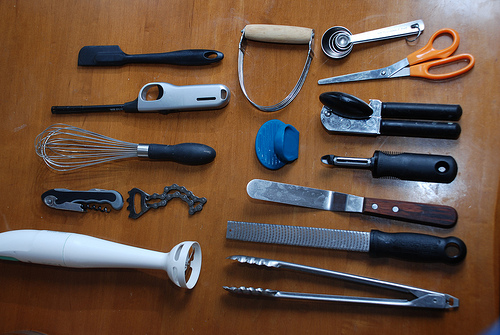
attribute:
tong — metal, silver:
[218, 260, 469, 302]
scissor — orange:
[297, 32, 482, 95]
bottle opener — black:
[132, 180, 227, 221]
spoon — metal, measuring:
[288, 13, 422, 69]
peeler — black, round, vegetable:
[302, 141, 475, 179]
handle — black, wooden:
[399, 84, 479, 132]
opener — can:
[312, 95, 465, 152]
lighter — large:
[33, 61, 232, 127]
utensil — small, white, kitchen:
[300, 14, 443, 73]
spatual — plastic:
[240, 114, 307, 172]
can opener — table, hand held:
[302, 80, 488, 159]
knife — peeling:
[309, 155, 465, 203]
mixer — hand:
[17, 98, 222, 200]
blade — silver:
[245, 176, 380, 226]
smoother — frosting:
[237, 124, 297, 175]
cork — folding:
[73, 35, 218, 85]